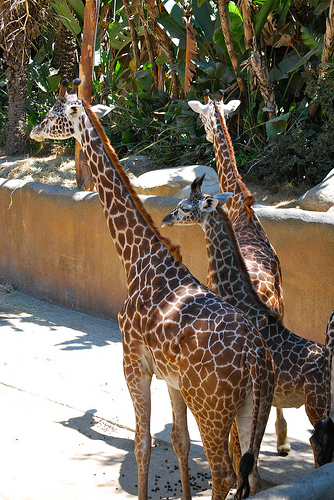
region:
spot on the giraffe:
[166, 269, 175, 278]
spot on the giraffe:
[200, 377, 214, 392]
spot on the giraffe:
[234, 352, 241, 366]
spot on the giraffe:
[198, 347, 217, 362]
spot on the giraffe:
[197, 333, 209, 349]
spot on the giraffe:
[234, 289, 245, 298]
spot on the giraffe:
[170, 354, 177, 361]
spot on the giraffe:
[201, 307, 211, 317]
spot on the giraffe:
[234, 281, 242, 290]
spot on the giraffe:
[229, 265, 235, 282]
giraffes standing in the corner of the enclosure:
[30, 93, 284, 301]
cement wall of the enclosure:
[15, 192, 106, 308]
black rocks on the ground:
[154, 465, 208, 497]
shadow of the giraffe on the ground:
[63, 402, 127, 454]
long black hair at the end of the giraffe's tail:
[312, 423, 332, 463]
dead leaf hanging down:
[181, 23, 197, 96]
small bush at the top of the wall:
[262, 135, 320, 189]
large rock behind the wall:
[301, 178, 325, 215]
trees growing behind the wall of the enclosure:
[111, 3, 168, 134]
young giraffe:
[173, 183, 299, 348]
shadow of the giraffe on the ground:
[50, 393, 150, 472]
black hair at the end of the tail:
[234, 452, 249, 494]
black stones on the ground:
[152, 461, 211, 497]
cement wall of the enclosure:
[26, 202, 85, 286]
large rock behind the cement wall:
[135, 154, 213, 206]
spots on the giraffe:
[188, 340, 232, 392]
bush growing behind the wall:
[267, 137, 319, 190]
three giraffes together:
[13, 67, 274, 289]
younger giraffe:
[157, 171, 311, 383]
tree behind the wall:
[7, 5, 43, 131]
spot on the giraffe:
[120, 230, 129, 243]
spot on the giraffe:
[212, 397, 222, 408]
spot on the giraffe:
[203, 396, 217, 406]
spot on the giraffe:
[230, 355, 241, 364]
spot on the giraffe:
[242, 357, 250, 366]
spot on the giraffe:
[288, 367, 296, 376]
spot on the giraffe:
[287, 354, 301, 367]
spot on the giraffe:
[156, 324, 164, 338]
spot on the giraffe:
[269, 342, 289, 348]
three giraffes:
[21, 97, 332, 496]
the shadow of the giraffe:
[62, 408, 116, 449]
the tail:
[244, 372, 268, 464]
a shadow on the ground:
[53, 332, 97, 351]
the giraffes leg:
[123, 410, 154, 497]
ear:
[202, 196, 221, 214]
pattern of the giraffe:
[171, 305, 238, 377]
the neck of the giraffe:
[207, 224, 244, 291]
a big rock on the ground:
[303, 179, 332, 205]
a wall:
[27, 188, 81, 296]